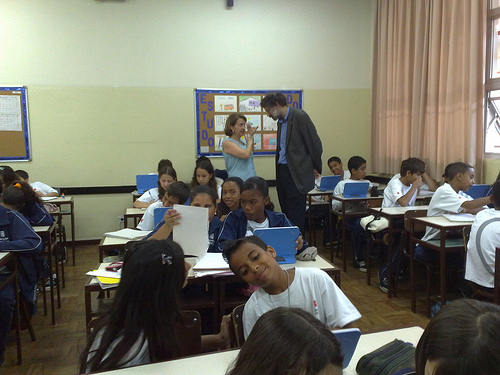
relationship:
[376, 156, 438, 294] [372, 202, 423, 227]
child at desk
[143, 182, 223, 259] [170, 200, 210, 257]
girl looking at a paper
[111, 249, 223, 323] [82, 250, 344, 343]
student at desk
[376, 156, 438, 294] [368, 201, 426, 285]
child at desk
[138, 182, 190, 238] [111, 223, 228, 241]
student at desk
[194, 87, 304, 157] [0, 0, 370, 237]
board on wall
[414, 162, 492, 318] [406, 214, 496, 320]
student sitting at desk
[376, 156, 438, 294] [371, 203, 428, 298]
child sitting at desk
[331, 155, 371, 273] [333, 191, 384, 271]
student sitting at desk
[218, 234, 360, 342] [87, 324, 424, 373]
boy sitting at desk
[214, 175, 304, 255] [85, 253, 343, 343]
girl sitting at desk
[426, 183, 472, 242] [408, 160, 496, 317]
white shirt on student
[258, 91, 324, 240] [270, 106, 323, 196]
man wearing gray jacket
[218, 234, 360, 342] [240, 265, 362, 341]
boy wearing shirt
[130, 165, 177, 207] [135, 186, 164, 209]
child wearing shirt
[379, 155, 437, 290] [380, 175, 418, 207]
child wearing shirt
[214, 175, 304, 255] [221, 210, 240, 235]
girl wearing jacket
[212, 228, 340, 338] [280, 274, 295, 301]
boy wearing necklace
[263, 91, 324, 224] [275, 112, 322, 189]
man wearing gray jacket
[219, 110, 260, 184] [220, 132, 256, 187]
woman wearing blouse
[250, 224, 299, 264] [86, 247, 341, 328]
laptop computer on desk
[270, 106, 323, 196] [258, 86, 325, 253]
gray jacket on man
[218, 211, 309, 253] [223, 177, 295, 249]
blue jacket on girl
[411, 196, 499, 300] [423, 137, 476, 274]
desk in front of girl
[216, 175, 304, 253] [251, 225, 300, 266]
girl in front of laptop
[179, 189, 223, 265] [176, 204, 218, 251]
girl holding paper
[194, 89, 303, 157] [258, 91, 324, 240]
board behind man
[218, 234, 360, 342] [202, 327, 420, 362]
boy at desk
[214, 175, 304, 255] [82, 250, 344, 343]
girl at desk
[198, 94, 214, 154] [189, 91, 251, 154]
estudo on brown surface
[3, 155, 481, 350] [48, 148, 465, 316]
children have dark hair